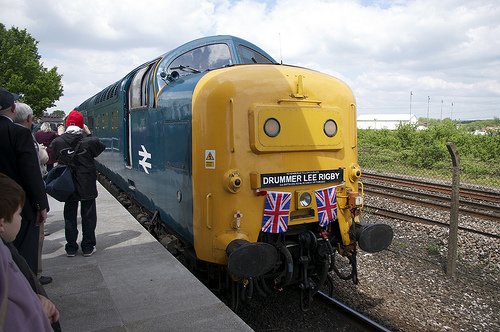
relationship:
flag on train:
[261, 188, 291, 233] [68, 33, 393, 314]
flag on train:
[314, 187, 338, 226] [68, 33, 393, 314]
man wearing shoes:
[48, 109, 106, 257] [64, 245, 98, 257]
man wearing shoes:
[10, 102, 53, 286] [38, 276, 54, 286]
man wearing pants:
[48, 109, 106, 257] [65, 199, 96, 256]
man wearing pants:
[10, 102, 53, 286] [37, 219, 44, 279]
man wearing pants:
[1, 90, 50, 277] [13, 222, 39, 278]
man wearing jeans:
[48, 109, 106, 257] [65, 199, 96, 256]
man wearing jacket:
[48, 109, 106, 257] [49, 126, 106, 200]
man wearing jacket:
[1, 90, 50, 277] [0, 116, 50, 220]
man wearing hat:
[48, 109, 106, 257] [66, 110, 85, 128]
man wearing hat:
[1, 90, 50, 277] [0, 89, 21, 110]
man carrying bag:
[48, 109, 106, 257] [45, 163, 76, 202]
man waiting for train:
[48, 109, 106, 257] [68, 33, 393, 314]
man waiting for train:
[10, 102, 53, 286] [68, 33, 393, 314]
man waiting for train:
[1, 90, 50, 277] [68, 33, 393, 314]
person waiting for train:
[35, 122, 59, 172] [68, 33, 393, 314]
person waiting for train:
[0, 172, 60, 331] [68, 33, 393, 314]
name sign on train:
[260, 169, 343, 189] [68, 33, 393, 314]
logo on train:
[137, 144, 152, 174] [68, 33, 393, 314]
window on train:
[167, 41, 232, 82] [68, 33, 393, 314]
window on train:
[238, 43, 276, 64] [68, 33, 393, 314]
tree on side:
[1, 22, 64, 117] [1, 2, 225, 305]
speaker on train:
[224, 238, 278, 277] [68, 33, 393, 314]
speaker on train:
[348, 221, 394, 253] [68, 33, 393, 314]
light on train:
[263, 117, 281, 137] [68, 33, 393, 314]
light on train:
[323, 119, 338, 137] [68, 33, 393, 314]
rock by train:
[436, 298, 442, 302] [68, 33, 393, 314]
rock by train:
[480, 251, 484, 256] [68, 33, 393, 314]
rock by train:
[444, 325, 451, 330] [68, 33, 393, 314]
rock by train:
[434, 210, 437, 215] [68, 33, 393, 314]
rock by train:
[385, 202, 387, 205] [68, 33, 393, 314]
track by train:
[363, 204, 499, 241] [68, 33, 393, 314]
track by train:
[310, 285, 393, 332] [68, 33, 393, 314]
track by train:
[359, 188, 498, 223] [68, 33, 393, 314]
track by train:
[358, 180, 499, 212] [68, 33, 393, 314]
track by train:
[360, 171, 499, 204] [68, 33, 393, 314]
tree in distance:
[1, 22, 64, 117] [0, 26, 66, 117]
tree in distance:
[52, 109, 66, 117] [0, 26, 66, 117]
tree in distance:
[493, 117, 499, 126] [356, 88, 499, 136]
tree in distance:
[419, 117, 425, 123] [356, 88, 499, 136]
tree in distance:
[443, 118, 451, 124] [356, 88, 499, 136]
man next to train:
[48, 109, 106, 257] [68, 33, 393, 314]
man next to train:
[10, 102, 53, 286] [68, 33, 393, 314]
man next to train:
[1, 90, 50, 277] [68, 33, 393, 314]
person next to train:
[35, 122, 59, 172] [68, 33, 393, 314]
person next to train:
[0, 172, 60, 331] [68, 33, 393, 314]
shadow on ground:
[41, 240, 255, 331] [40, 178, 253, 330]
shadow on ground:
[95, 229, 142, 249] [40, 178, 253, 330]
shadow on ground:
[40, 237, 66, 257] [40, 178, 253, 330]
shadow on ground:
[42, 216, 83, 236] [40, 178, 253, 330]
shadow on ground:
[47, 214, 55, 219] [40, 178, 253, 330]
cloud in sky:
[274, 0, 465, 62] [1, 0, 499, 120]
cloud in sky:
[1, 1, 216, 49] [1, 0, 499, 120]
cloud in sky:
[407, 28, 498, 70] [1, 0, 499, 120]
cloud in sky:
[351, 73, 497, 93] [1, 0, 499, 120]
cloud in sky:
[57, 80, 104, 92] [1, 0, 499, 120]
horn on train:
[159, 71, 179, 80] [68, 33, 393, 314]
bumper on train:
[224, 238, 278, 277] [68, 33, 393, 314]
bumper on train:
[348, 221, 394, 253] [68, 33, 393, 314]